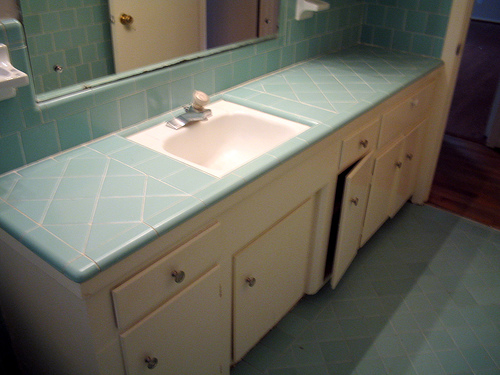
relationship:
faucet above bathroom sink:
[170, 88, 239, 134] [152, 110, 297, 175]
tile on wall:
[1, 1, 452, 173] [0, 5, 448, 155]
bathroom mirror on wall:
[17, 2, 291, 103] [0, 0, 366, 173]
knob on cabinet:
[238, 264, 263, 295] [301, 126, 409, 291]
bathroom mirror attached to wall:
[17, 2, 291, 103] [0, 0, 366, 173]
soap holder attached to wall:
[1, 45, 29, 110] [2, 105, 47, 167]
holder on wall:
[296, 3, 328, 22] [285, 0, 442, 52]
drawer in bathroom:
[111, 221, 221, 327] [4, 2, 494, 370]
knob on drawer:
[169, 263, 190, 283] [106, 217, 228, 328]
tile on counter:
[1, 1, 452, 173] [0, 37, 445, 282]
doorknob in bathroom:
[108, 3, 144, 41] [4, 2, 494, 370]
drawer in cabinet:
[111, 221, 221, 327] [110, 264, 224, 372]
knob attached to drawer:
[169, 263, 190, 283] [109, 141, 348, 328]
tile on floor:
[388, 252, 446, 280] [245, 191, 497, 360]